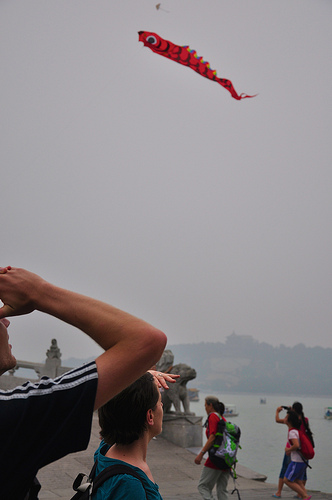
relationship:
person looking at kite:
[69, 370, 181, 499] [138, 30, 258, 101]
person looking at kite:
[2, 266, 168, 498] [138, 30, 258, 101]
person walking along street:
[195, 396, 228, 499] [37, 407, 332, 499]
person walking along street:
[217, 402, 226, 412] [37, 407, 332, 499]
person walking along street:
[283, 414, 311, 500] [37, 407, 332, 499]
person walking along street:
[276, 402, 307, 500] [37, 407, 332, 499]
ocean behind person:
[173, 391, 332, 494] [195, 396, 228, 499]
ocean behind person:
[173, 391, 332, 494] [217, 402, 226, 412]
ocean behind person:
[173, 391, 332, 494] [276, 402, 307, 500]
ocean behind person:
[173, 391, 332, 494] [283, 414, 311, 500]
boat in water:
[225, 404, 239, 418] [173, 391, 332, 494]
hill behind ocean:
[60, 332, 330, 397] [173, 391, 332, 494]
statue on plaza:
[149, 349, 202, 446] [1, 361, 330, 499]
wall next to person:
[0, 339, 202, 447] [217, 402, 226, 412]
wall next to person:
[0, 339, 202, 447] [195, 396, 228, 499]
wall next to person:
[0, 339, 202, 447] [276, 402, 307, 500]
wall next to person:
[0, 339, 202, 447] [283, 414, 311, 500]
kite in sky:
[138, 30, 258, 101] [0, 0, 331, 365]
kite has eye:
[138, 30, 258, 101] [146, 36, 157, 47]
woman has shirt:
[69, 370, 181, 499] [95, 438, 162, 499]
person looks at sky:
[2, 266, 168, 498] [0, 0, 331, 365]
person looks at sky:
[69, 370, 181, 499] [0, 0, 331, 365]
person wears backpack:
[69, 370, 181, 499] [71, 459, 148, 500]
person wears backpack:
[195, 396, 228, 499] [210, 420, 241, 467]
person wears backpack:
[283, 414, 311, 500] [299, 430, 314, 461]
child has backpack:
[283, 414, 311, 500] [299, 430, 314, 461]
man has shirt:
[2, 266, 168, 498] [0, 360, 98, 499]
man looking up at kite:
[2, 266, 168, 498] [138, 30, 258, 101]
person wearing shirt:
[195, 396, 228, 499] [204, 413, 226, 470]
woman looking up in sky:
[69, 370, 181, 499] [0, 0, 331, 365]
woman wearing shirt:
[69, 370, 181, 499] [95, 438, 162, 499]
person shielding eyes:
[2, 266, 168, 498] [0, 307, 4, 324]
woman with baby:
[283, 414, 311, 500] [302, 428, 312, 438]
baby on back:
[302, 428, 312, 438] [301, 417, 309, 433]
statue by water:
[149, 349, 202, 446] [173, 391, 332, 494]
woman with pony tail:
[276, 402, 307, 500] [299, 411, 314, 435]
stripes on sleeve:
[0, 360, 97, 400] [0, 360, 98, 470]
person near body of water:
[217, 402, 226, 412] [173, 391, 332, 494]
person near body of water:
[195, 396, 228, 499] [173, 391, 332, 494]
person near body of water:
[276, 402, 307, 500] [173, 391, 332, 494]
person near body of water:
[283, 414, 311, 500] [173, 391, 332, 494]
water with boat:
[173, 391, 332, 494] [188, 389, 200, 403]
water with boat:
[173, 391, 332, 494] [225, 404, 239, 418]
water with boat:
[173, 391, 332, 494] [260, 399, 266, 406]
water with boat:
[173, 391, 332, 494] [326, 411, 331, 420]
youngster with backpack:
[283, 414, 311, 500] [299, 430, 314, 461]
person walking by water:
[217, 402, 226, 412] [173, 391, 332, 494]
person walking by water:
[195, 396, 228, 499] [173, 391, 332, 494]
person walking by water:
[276, 402, 307, 500] [173, 391, 332, 494]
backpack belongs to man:
[210, 420, 241, 467] [195, 396, 228, 499]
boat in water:
[188, 389, 200, 403] [173, 391, 332, 494]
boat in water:
[260, 399, 266, 406] [173, 391, 332, 494]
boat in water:
[326, 411, 331, 420] [173, 391, 332, 494]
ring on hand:
[155, 373, 162, 378] [147, 369, 180, 389]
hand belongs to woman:
[147, 369, 180, 389] [69, 370, 181, 499]